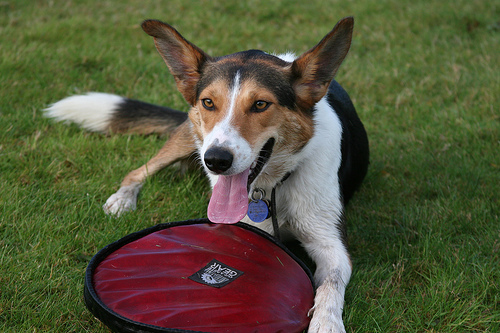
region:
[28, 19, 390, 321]
A dog laydown in the grass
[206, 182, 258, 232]
Tongue of the dog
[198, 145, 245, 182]
Black color nose of the dog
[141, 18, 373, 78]
Black and brown color ear of the dog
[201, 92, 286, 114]
Eyes of the dog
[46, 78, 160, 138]
Tail of the dog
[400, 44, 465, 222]
Green color grass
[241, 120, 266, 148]
Cheek of the dog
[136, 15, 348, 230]
Head of the dog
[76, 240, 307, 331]
A red and black color stuff in front of the dog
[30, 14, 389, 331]
dog laying on the grass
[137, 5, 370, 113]
two long ears sticking off the head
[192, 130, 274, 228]
mouth is open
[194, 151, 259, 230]
light pink tongue hanging out of the mouth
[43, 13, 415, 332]
brown, white, and black dog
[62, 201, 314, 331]
red and black toy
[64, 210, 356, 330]
toy laying by the paw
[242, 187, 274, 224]
tag on the collar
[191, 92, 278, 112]
two brown and black eyes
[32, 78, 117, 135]
tip of the tail is white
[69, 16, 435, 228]
a brown black tan dog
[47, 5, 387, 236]
a dog panting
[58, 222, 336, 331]
a red and black frisbee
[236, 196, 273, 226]
a vlue metal on collar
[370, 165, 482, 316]
green grass in a field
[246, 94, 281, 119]
a eye of a dog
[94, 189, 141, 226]
a white back paw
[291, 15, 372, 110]
a dogs left ear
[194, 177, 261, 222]
a pink tongue of a dog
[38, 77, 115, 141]
a white tip of a tail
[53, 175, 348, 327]
the dog has a frisbee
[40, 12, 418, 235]
this dog is laying in the grass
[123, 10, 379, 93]
the dogs ears are pointed upward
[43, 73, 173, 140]
the dog has a white tipped tail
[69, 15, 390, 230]
the dog is white, brown and black in color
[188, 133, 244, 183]
the dogs nose is black in color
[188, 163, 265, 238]
the dog is sticking its tongue out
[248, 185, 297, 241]
the dog is wearing a collar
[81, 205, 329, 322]
the dogs Frisbee is red and black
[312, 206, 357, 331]
this is the dogs leg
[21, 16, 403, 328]
A dog with a disc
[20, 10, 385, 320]
A dog with a frisbee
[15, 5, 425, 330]
a dog laying on the ground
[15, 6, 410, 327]
A dog laying on the ground with a frisbee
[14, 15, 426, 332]
A dog laying on the ground with a round disc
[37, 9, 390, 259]
A dog panting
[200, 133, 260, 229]
a dog's tongue hanging out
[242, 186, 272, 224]
A dog tag on a dog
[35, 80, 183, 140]
A dog's tail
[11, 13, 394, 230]
A dog with his tongue hanging out